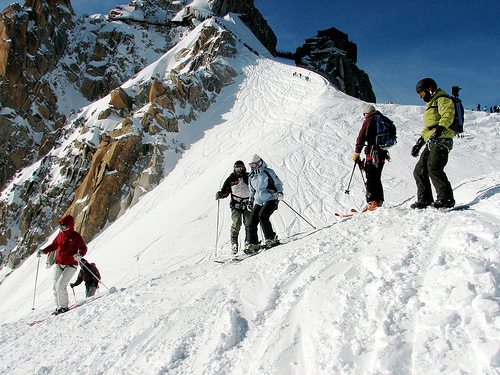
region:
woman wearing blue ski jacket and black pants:
[244, 150, 285, 262]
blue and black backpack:
[451, 92, 471, 136]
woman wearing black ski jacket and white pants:
[35, 212, 92, 321]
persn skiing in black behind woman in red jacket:
[55, 242, 106, 303]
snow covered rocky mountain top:
[33, 13, 245, 218]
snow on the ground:
[175, 249, 488, 363]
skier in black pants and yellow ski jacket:
[403, 75, 472, 217]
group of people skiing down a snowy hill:
[27, 66, 472, 334]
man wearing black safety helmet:
[413, 76, 440, 106]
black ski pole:
[341, 158, 363, 220]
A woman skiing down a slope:
[36, 215, 108, 348]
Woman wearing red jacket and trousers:
[30, 213, 94, 318]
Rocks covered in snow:
[14, 47, 216, 229]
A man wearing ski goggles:
[225, 154, 255, 249]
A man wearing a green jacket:
[402, 79, 458, 201]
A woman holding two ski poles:
[345, 100, 407, 217]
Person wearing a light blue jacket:
[241, 147, 288, 243]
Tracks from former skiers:
[230, 64, 312, 157]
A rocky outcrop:
[301, 22, 378, 104]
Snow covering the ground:
[334, 258, 459, 333]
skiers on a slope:
[27, 53, 483, 366]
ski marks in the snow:
[287, 73, 356, 209]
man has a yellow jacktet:
[421, 85, 464, 136]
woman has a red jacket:
[38, 210, 83, 274]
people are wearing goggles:
[219, 141, 273, 186]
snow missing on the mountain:
[23, 83, 197, 231]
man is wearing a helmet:
[415, 71, 450, 104]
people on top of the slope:
[430, 71, 498, 111]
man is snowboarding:
[417, 72, 487, 253]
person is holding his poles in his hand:
[318, 133, 387, 198]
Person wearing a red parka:
[29, 209, 95, 274]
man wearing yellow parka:
[410, 77, 465, 153]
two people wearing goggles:
[196, 139, 313, 274]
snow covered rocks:
[50, 20, 220, 154]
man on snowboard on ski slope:
[407, 80, 467, 209]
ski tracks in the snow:
[278, 90, 332, 186]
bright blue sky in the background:
[375, 15, 478, 62]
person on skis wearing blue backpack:
[343, 90, 400, 207]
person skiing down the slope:
[31, 207, 91, 314]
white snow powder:
[320, 256, 422, 358]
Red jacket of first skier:
[40, 206, 88, 262]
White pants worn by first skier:
[47, 265, 73, 308]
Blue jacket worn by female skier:
[242, 170, 282, 211]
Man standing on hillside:
[408, 71, 471, 211]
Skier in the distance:
[68, 255, 109, 295]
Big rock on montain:
[281, 15, 381, 105]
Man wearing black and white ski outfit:
[210, 150, 251, 248]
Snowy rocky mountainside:
[1, 1, 226, 256]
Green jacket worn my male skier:
[417, 95, 452, 142]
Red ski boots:
[356, 193, 383, 216]